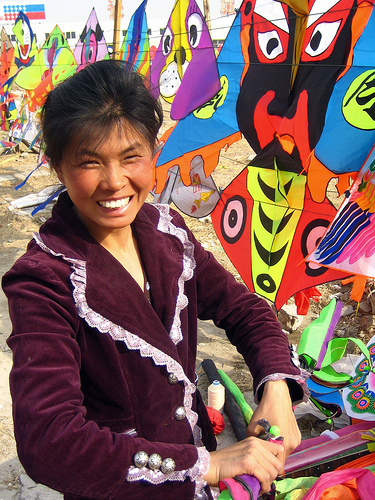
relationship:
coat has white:
[2, 192, 311, 499] [150, 201, 198, 343]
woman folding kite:
[0, 58, 302, 500] [226, 421, 285, 499]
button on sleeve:
[136, 450, 147, 466] [9, 333, 211, 499]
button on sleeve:
[149, 452, 161, 470] [9, 333, 211, 499]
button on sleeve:
[163, 458, 175, 471] [9, 333, 211, 499]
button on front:
[177, 407, 185, 418] [3, 207, 217, 458]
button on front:
[170, 371, 180, 382] [3, 207, 217, 458]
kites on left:
[0, 0, 113, 166] [0, 0, 168, 499]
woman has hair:
[0, 58, 302, 500] [37, 58, 163, 173]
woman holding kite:
[0, 58, 302, 500] [226, 421, 285, 499]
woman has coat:
[0, 58, 302, 500] [2, 192, 311, 499]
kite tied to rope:
[149, 0, 223, 121] [7, 4, 375, 51]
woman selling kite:
[0, 58, 302, 500] [226, 421, 285, 499]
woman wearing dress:
[0, 58, 302, 500] [0, 193, 305, 500]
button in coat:
[170, 371, 180, 382] [2, 192, 311, 499]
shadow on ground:
[3, 458, 67, 499] [0, 128, 71, 499]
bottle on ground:
[207, 381, 223, 436] [194, 317, 259, 454]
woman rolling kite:
[0, 58, 302, 500] [226, 421, 285, 499]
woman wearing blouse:
[0, 58, 302, 500] [2, 192, 311, 499]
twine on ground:
[207, 408, 226, 433] [194, 317, 259, 454]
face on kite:
[160, 0, 203, 105] [149, 0, 223, 121]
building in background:
[4, 1, 368, 133] [1, 4, 372, 137]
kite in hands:
[226, 421, 285, 499] [220, 398, 303, 491]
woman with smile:
[0, 58, 302, 500] [94, 194, 134, 215]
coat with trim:
[2, 192, 311, 499] [128, 446, 216, 497]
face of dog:
[160, 0, 203, 105] [149, 0, 223, 121]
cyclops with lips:
[11, 13, 40, 80] [18, 44, 32, 57]